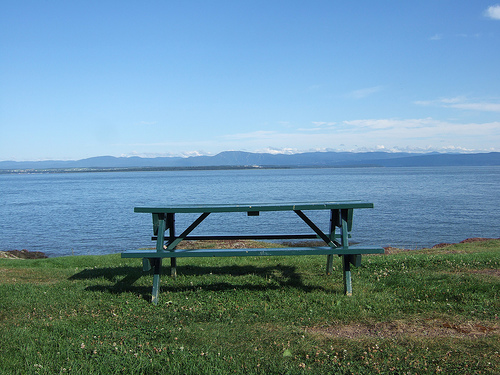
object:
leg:
[149, 218, 165, 302]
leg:
[340, 220, 358, 296]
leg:
[168, 212, 178, 279]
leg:
[325, 210, 336, 278]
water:
[0, 166, 500, 257]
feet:
[343, 254, 354, 296]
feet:
[150, 256, 162, 304]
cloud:
[315, 107, 498, 129]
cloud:
[239, 129, 497, 153]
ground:
[0, 236, 500, 375]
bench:
[120, 201, 388, 304]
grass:
[0, 234, 500, 375]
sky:
[2, 0, 500, 151]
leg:
[341, 257, 352, 297]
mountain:
[0, 143, 500, 170]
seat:
[119, 246, 385, 260]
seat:
[151, 233, 351, 241]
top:
[134, 200, 375, 213]